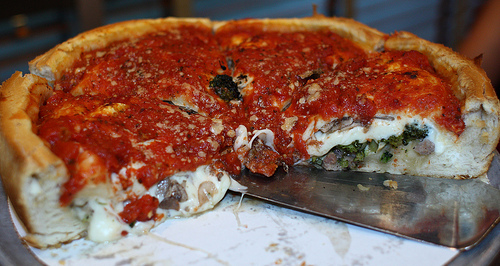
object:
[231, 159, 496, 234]
pizza cutter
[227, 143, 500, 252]
board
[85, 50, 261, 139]
seasoning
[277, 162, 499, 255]
spatula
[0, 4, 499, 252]
pizza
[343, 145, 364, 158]
broccoli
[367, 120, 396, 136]
cheese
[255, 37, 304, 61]
sauce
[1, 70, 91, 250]
crust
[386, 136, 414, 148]
spinach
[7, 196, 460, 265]
cardboard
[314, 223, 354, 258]
grease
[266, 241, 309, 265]
grease stains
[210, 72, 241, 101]
food item